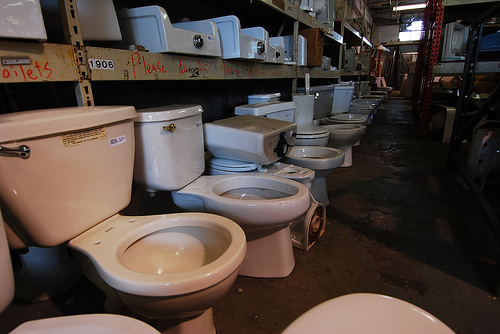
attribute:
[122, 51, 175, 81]
word — please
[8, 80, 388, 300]
toilet — white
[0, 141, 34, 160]
handle — silver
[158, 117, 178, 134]
handle — silver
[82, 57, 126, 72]
numbers — 1906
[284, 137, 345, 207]
toilet — white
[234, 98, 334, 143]
toilet — white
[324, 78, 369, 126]
toilet — white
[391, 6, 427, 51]
window — high, exterior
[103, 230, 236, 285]
bowl — toilet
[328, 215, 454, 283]
floor — concrete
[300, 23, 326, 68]
box — cardboard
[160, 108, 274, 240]
toilet — white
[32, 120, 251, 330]
toilet — pink, white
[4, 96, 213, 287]
toilet — white, pink, porcelain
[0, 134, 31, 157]
handle — silver, flush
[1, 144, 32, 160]
handle — gold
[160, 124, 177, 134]
handle — gold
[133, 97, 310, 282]
toilet — white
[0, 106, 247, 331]
toilet — white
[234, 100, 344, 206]
toilet — white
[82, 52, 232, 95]
shelving — metal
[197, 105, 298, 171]
tank — toilet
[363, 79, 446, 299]
floor — dirty, concrete